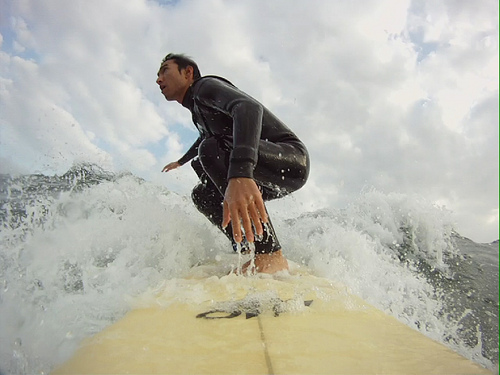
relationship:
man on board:
[145, 42, 323, 284] [104, 205, 450, 373]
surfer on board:
[157, 47, 321, 371] [181, 273, 296, 360]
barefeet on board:
[213, 212, 361, 312] [44, 273, 499, 374]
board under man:
[44, 273, 499, 374] [153, 48, 317, 278]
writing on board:
[190, 288, 301, 328] [44, 273, 499, 374]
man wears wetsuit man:
[145, 42, 323, 284] [150, 52, 310, 278]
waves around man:
[1, 159, 498, 374] [145, 42, 323, 284]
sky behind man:
[10, 16, 479, 176] [145, 42, 323, 284]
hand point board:
[213, 179, 278, 251] [44, 273, 499, 374]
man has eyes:
[145, 42, 323, 284] [160, 64, 167, 75]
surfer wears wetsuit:
[153, 53, 310, 295] [178, 75, 308, 253]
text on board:
[190, 289, 317, 323] [44, 273, 499, 374]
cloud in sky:
[338, 32, 458, 174] [10, 16, 479, 176]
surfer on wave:
[148, 46, 310, 276] [0, 173, 499, 373]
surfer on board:
[148, 45, 320, 287] [44, 273, 499, 374]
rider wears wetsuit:
[155, 51, 310, 276] [178, 75, 308, 253]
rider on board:
[155, 51, 310, 276] [44, 273, 499, 374]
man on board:
[153, 48, 317, 278] [44, 273, 499, 374]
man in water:
[123, 32, 342, 252] [330, 195, 445, 310]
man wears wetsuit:
[139, 55, 319, 282] [212, 82, 253, 165]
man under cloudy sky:
[153, 48, 317, 278] [4, 2, 498, 225]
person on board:
[137, 45, 332, 280] [44, 273, 499, 374]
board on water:
[44, 273, 499, 374] [10, 152, 490, 364]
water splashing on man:
[10, 152, 490, 364] [153, 48, 317, 278]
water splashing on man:
[10, 152, 490, 364] [139, 55, 319, 282]